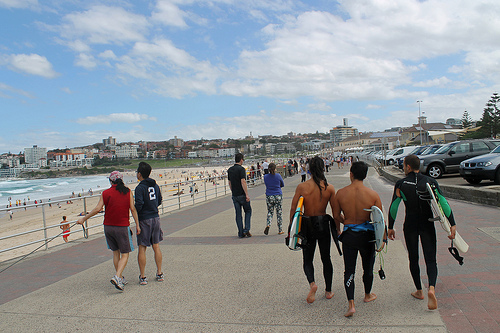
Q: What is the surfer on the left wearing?
A: Black wetsuit.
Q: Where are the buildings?
A: On the seashore.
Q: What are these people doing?
A: Walking on the road.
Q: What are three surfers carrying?
A: Surf boards.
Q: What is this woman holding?
A: Rope.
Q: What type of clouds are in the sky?
A: Fluffy white.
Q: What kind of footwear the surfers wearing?
A: They are with bare feet.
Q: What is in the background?
A: Buildings.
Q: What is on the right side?
A: A parking lot for cars.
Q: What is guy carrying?
A: Surfboard.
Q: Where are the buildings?
A: In distance.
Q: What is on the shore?
A: A lot of people.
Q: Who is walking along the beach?
A: Men and women.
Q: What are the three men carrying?
A: Surfboards.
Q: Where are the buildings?
A: Along the shore.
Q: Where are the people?
A: At the beach.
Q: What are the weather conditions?
A: Cloudy.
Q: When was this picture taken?
A: In the daytime.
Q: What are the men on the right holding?
A: Surfboards.